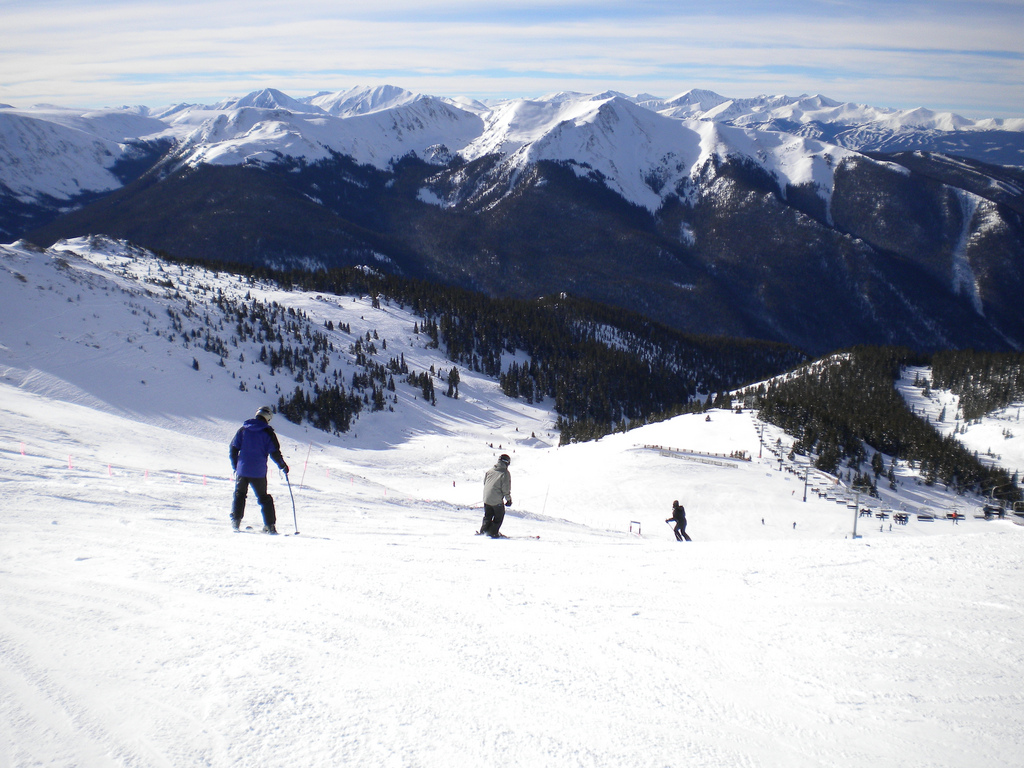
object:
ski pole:
[285, 473, 301, 534]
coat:
[228, 418, 286, 478]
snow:
[0, 83, 1024, 217]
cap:
[0, 84, 1024, 215]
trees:
[351, 351, 408, 420]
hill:
[0, 234, 818, 518]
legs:
[230, 474, 276, 525]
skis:
[228, 494, 299, 537]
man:
[480, 454, 512, 539]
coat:
[484, 461, 514, 506]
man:
[228, 405, 288, 535]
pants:
[480, 503, 505, 535]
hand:
[280, 466, 289, 475]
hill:
[0, 493, 1024, 768]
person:
[666, 500, 693, 543]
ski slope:
[0, 516, 1024, 766]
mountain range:
[0, 83, 1024, 351]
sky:
[0, 0, 1024, 118]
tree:
[777, 386, 884, 491]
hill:
[469, 351, 1024, 616]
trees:
[704, 167, 824, 252]